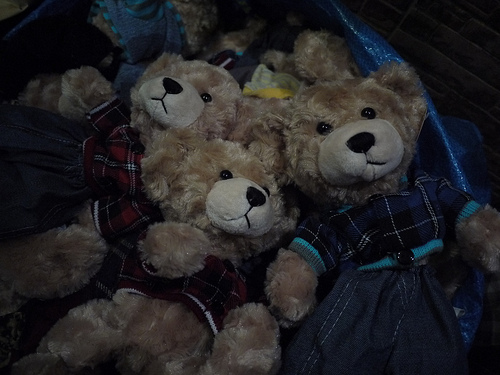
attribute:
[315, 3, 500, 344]
cloth — blue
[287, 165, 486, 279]
sweater — blue, plaid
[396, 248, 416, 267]
button — shiny, black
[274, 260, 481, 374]
shorts — grey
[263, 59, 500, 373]
teddy bear — different, furry, brown, on the right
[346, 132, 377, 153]
nose — cloth, black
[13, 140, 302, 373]
teddy bear — different, center, in middle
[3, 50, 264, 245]
teddy bear — different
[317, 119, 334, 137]
eye — plastic, round, black, shiny, dark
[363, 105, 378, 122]
eye — dark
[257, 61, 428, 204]
head — brown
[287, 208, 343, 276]
sleeve — blue, grey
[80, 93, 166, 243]
shirt — red, striped, plaid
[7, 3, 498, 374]
bag — large, plastic, blue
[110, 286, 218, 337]
stripe — white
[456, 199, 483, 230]
trim — light blue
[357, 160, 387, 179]
mouth — stitched, black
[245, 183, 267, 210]
nose — black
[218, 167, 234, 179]
eye — dark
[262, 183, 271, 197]
eye — dark